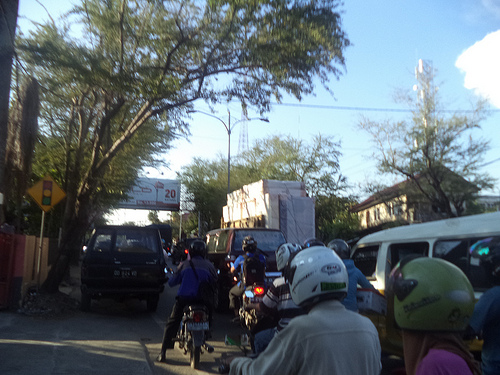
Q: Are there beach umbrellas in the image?
A: No, there are no beach umbrellas.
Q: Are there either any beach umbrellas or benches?
A: No, there are no beach umbrellas or benches.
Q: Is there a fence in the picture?
A: No, there are no fences.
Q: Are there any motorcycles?
A: Yes, there is a motorcycle.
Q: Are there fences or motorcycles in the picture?
A: Yes, there is a motorcycle.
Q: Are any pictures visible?
A: No, there are no pictures.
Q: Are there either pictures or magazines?
A: No, there are no pictures or magazines.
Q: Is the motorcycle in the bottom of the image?
A: Yes, the motorcycle is in the bottom of the image.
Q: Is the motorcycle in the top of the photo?
A: No, the motorcycle is in the bottom of the image.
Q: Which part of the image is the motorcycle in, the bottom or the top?
A: The motorcycle is in the bottom of the image.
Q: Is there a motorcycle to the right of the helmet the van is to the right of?
A: No, the motorcycle is to the left of the helmet.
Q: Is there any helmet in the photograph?
A: Yes, there is a helmet.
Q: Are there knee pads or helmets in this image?
A: Yes, there is a helmet.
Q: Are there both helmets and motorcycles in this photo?
A: Yes, there are both a helmet and a motorcycle.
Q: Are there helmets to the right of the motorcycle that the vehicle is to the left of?
A: Yes, there is a helmet to the right of the motorcycle.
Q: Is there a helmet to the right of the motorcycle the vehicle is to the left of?
A: Yes, there is a helmet to the right of the motorcycle.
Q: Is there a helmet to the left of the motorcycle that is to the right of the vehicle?
A: No, the helmet is to the right of the motorcycle.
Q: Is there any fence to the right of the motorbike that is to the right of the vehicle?
A: No, there is a helmet to the right of the motorbike.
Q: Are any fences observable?
A: No, there are no fences.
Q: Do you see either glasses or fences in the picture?
A: No, there are no fences or glasses.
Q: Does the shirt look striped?
A: Yes, the shirt is striped.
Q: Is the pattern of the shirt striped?
A: Yes, the shirt is striped.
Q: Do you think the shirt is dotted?
A: No, the shirt is striped.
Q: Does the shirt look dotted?
A: No, the shirt is striped.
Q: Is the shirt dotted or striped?
A: The shirt is striped.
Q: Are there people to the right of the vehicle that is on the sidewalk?
A: Yes, there is a person to the right of the vehicle.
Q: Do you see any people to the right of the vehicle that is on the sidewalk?
A: Yes, there is a person to the right of the vehicle.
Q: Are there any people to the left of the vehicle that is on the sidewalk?
A: No, the person is to the right of the vehicle.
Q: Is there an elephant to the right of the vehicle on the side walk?
A: No, there is a person to the right of the vehicle.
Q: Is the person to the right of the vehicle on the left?
A: Yes, the person is to the right of the vehicle.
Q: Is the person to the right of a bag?
A: No, the person is to the right of the vehicle.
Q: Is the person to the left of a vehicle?
A: No, the person is to the right of a vehicle.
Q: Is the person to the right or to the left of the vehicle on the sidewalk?
A: The person is to the right of the vehicle.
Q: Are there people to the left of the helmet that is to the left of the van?
A: Yes, there is a person to the left of the helmet.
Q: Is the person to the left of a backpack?
A: No, the person is to the left of the helmet.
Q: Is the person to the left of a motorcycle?
A: Yes, the person is to the left of a motorcycle.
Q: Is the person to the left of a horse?
A: No, the person is to the left of a motorcycle.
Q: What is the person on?
A: The person is on the motorbike.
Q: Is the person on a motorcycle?
A: Yes, the person is on a motorcycle.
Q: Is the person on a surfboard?
A: No, the person is on a motorcycle.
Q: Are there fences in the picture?
A: No, there are no fences.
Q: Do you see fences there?
A: No, there are no fences.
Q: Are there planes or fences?
A: No, there are no fences or planes.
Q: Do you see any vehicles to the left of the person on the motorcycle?
A: Yes, there is a vehicle to the left of the person.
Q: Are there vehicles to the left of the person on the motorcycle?
A: Yes, there is a vehicle to the left of the person.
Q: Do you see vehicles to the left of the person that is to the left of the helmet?
A: Yes, there is a vehicle to the left of the person.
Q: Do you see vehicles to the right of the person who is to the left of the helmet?
A: No, the vehicle is to the left of the person.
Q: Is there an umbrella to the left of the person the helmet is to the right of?
A: No, there is a vehicle to the left of the person.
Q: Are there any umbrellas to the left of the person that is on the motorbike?
A: No, there is a vehicle to the left of the person.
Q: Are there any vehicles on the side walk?
A: Yes, there is a vehicle on the side walk.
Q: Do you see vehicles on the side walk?
A: Yes, there is a vehicle on the side walk.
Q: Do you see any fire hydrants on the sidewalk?
A: No, there is a vehicle on the sidewalk.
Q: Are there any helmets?
A: Yes, there is a helmet.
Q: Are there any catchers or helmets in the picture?
A: Yes, there is a helmet.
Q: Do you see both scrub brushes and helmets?
A: No, there is a helmet but no scrub brushes.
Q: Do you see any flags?
A: No, there are no flags.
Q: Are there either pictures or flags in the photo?
A: No, there are no flags or pictures.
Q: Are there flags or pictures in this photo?
A: No, there are no flags or pictures.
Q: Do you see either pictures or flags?
A: No, there are no flags or pictures.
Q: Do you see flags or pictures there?
A: No, there are no flags or pictures.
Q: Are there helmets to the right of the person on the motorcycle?
A: Yes, there is a helmet to the right of the person.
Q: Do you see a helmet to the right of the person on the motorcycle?
A: Yes, there is a helmet to the right of the person.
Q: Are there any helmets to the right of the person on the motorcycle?
A: Yes, there is a helmet to the right of the person.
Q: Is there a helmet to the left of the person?
A: No, the helmet is to the right of the person.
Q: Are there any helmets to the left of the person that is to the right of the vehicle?
A: No, the helmet is to the right of the person.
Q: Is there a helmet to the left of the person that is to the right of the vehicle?
A: No, the helmet is to the right of the person.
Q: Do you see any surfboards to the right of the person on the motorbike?
A: No, there is a helmet to the right of the person.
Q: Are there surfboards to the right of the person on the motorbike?
A: No, there is a helmet to the right of the person.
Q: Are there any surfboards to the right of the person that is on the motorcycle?
A: No, there is a helmet to the right of the person.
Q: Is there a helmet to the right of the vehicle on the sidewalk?
A: Yes, there is a helmet to the right of the vehicle.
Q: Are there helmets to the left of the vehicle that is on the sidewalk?
A: No, the helmet is to the right of the vehicle.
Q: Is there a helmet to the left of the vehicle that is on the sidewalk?
A: No, the helmet is to the right of the vehicle.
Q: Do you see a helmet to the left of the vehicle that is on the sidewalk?
A: No, the helmet is to the right of the vehicle.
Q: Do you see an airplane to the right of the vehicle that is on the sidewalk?
A: No, there is a helmet to the right of the vehicle.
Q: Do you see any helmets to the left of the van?
A: Yes, there is a helmet to the left of the van.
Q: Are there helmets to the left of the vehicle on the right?
A: Yes, there is a helmet to the left of the van.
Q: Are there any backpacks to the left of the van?
A: No, there is a helmet to the left of the van.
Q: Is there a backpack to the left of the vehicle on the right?
A: No, there is a helmet to the left of the van.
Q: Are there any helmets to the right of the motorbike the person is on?
A: Yes, there is a helmet to the right of the motorcycle.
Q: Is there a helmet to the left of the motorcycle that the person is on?
A: No, the helmet is to the right of the motorbike.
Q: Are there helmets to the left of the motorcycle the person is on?
A: No, the helmet is to the right of the motorbike.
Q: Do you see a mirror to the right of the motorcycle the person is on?
A: No, there is a helmet to the right of the motorbike.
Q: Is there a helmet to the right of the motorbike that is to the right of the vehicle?
A: Yes, there is a helmet to the right of the motorbike.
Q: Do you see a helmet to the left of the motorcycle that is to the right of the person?
A: No, the helmet is to the right of the motorbike.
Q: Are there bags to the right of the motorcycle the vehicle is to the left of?
A: No, there is a helmet to the right of the motorcycle.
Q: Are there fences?
A: No, there are no fences.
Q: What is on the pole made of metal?
A: The sign is on the pole.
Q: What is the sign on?
A: The sign is on the pole.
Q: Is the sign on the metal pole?
A: Yes, the sign is on the pole.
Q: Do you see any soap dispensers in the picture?
A: No, there are no soap dispensers.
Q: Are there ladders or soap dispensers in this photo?
A: No, there are no soap dispensers or ladders.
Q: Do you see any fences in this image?
A: No, there are no fences.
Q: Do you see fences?
A: No, there are no fences.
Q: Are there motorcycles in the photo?
A: Yes, there is a motorcycle.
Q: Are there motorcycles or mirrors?
A: Yes, there is a motorcycle.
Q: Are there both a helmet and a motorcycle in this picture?
A: Yes, there are both a motorcycle and a helmet.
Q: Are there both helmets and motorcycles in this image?
A: Yes, there are both a motorcycle and a helmet.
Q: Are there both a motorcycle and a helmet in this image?
A: Yes, there are both a motorcycle and a helmet.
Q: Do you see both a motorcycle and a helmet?
A: Yes, there are both a motorcycle and a helmet.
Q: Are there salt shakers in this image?
A: No, there are no salt shakers.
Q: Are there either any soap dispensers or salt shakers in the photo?
A: No, there are no salt shakers or soap dispensers.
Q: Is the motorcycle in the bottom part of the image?
A: Yes, the motorcycle is in the bottom of the image.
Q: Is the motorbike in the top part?
A: No, the motorbike is in the bottom of the image.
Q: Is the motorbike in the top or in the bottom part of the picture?
A: The motorbike is in the bottom of the image.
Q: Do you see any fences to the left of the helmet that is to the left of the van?
A: No, there is a motorcycle to the left of the helmet.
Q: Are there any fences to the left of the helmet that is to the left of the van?
A: No, there is a motorcycle to the left of the helmet.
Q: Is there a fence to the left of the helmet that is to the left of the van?
A: No, there is a motorcycle to the left of the helmet.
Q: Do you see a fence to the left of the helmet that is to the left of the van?
A: No, there is a motorcycle to the left of the helmet.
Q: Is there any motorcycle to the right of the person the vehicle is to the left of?
A: Yes, there is a motorcycle to the right of the person.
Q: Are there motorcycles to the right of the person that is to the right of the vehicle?
A: Yes, there is a motorcycle to the right of the person.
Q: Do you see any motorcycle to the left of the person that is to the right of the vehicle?
A: No, the motorcycle is to the right of the person.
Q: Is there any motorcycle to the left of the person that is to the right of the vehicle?
A: No, the motorcycle is to the right of the person.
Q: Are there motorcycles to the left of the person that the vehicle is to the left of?
A: No, the motorcycle is to the right of the person.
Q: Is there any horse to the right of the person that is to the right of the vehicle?
A: No, there is a motorcycle to the right of the person.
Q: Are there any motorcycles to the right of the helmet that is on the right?
A: No, the motorcycle is to the left of the helmet.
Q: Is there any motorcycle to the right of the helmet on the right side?
A: No, the motorcycle is to the left of the helmet.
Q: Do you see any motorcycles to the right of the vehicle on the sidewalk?
A: Yes, there is a motorcycle to the right of the vehicle.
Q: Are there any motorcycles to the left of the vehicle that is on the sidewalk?
A: No, the motorcycle is to the right of the vehicle.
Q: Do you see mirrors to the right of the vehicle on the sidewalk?
A: No, there is a motorcycle to the right of the vehicle.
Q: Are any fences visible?
A: No, there are no fences.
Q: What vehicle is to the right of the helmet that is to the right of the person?
A: The vehicle is a van.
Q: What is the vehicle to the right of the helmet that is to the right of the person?
A: The vehicle is a van.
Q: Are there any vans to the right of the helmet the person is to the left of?
A: Yes, there is a van to the right of the helmet.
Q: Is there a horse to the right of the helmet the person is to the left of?
A: No, there is a van to the right of the helmet.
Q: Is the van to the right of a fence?
A: No, the van is to the right of the helmet.